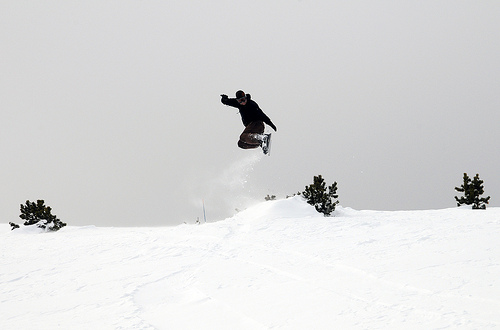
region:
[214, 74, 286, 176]
the boarder flying through the air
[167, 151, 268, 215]
the board kicking up snow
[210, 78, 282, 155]
the snowboarder does a trick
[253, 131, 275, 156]
the snow on the boarders boats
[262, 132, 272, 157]
the black snowboard on the man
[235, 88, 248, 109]
the cap on the mans head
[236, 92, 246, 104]
the pair of googles on the mans face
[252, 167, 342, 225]
the snow covered shrub on the hill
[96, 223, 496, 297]
the white snow on the ground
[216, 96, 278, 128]
the balck jacket of the snowboarder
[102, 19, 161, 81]
this is the sky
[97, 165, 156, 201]
the sky is bright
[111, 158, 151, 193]
the sky has clouds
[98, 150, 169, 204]
the clouds are white in color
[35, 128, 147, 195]
the clouds are big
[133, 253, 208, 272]
this is the snow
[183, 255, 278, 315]
the snow is white in color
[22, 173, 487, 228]
these are some trees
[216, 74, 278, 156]
this is a man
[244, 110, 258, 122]
the sweater is black in color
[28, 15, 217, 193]
A CLOUDY COLD DAY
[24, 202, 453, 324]
WHITE SNOW ON A SKI HILL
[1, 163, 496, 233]
THREE GREEN TREES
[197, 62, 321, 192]
SNOW BOARDER CATCHING AIR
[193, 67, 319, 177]
SNOW BOARDER JUMPING A HILL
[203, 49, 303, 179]
SNOW BOARDING BENDING KNEES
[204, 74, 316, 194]
SNOW BOARDER BENDING KNEES IN AIR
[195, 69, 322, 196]
SNOW BOARDER GLIDING THROUGH AIR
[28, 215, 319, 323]
SKI COURSE IN THE SNOW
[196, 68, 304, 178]
SNOW BOARDER WEARING ALL BLACK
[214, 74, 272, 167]
this is a boy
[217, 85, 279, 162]
the boy is skating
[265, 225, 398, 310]
this is the snow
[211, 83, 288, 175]
the boy is on air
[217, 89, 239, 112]
this is the hand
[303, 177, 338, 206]
these are the grass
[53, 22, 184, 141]
this is the sky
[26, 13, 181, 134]
the sky is white in color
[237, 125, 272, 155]
these are the legs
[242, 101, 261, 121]
the jamper is black in color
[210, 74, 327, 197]
A skier in the air.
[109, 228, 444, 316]
Snow on the ground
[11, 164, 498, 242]
Small trees on the ground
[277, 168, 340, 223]
Snow on the trees.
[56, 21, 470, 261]
The photo is black and white.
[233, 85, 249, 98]
The person is wearing a ski cap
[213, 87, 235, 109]
Arms is spread out.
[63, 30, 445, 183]
The sky is clear.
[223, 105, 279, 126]
Person wearing a dark jacket.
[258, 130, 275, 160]
Person wearing skis.